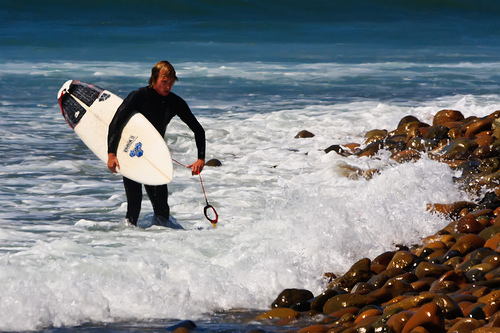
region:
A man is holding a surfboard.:
[50, 53, 226, 235]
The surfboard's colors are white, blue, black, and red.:
[50, 71, 175, 186]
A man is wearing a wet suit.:
[100, 71, 207, 231]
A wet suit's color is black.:
[100, 76, 207, 236]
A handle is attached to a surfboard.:
[162, 145, 222, 230]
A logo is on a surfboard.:
[121, 131, 150, 163]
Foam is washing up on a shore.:
[0, 85, 499, 332]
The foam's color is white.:
[0, 85, 498, 332]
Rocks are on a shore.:
[160, 96, 498, 332]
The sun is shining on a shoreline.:
[0, 51, 498, 331]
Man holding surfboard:
[87, 71, 202, 249]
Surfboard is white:
[66, 62, 191, 197]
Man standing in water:
[79, 86, 219, 230]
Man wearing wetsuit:
[98, 42, 163, 226]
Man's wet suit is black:
[60, 60, 192, 247]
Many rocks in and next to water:
[368, 86, 465, 278]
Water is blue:
[228, 38, 414, 88]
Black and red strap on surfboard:
[119, 110, 248, 252]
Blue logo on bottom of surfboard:
[127, 137, 164, 194]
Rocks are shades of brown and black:
[373, 254, 446, 329]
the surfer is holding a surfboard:
[53, 41, 298, 276]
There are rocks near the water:
[73, 29, 491, 330]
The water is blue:
[25, 9, 432, 264]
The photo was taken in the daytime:
[30, 8, 465, 289]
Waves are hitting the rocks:
[221, 85, 496, 322]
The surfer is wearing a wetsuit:
[56, 37, 276, 267]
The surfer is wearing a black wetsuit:
[50, 45, 260, 290]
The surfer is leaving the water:
[62, 32, 307, 284]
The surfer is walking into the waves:
[15, 16, 457, 324]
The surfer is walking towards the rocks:
[44, 36, 476, 323]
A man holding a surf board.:
[36, 51, 245, 279]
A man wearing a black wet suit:
[76, 44, 229, 296]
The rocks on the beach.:
[347, 76, 497, 330]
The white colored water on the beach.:
[50, 129, 439, 282]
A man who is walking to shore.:
[51, 55, 274, 219]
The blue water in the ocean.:
[36, 36, 480, 268]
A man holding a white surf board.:
[48, 42, 315, 325]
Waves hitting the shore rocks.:
[270, 112, 499, 293]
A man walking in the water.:
[40, 52, 315, 317]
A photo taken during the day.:
[31, 27, 416, 299]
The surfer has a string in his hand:
[121, 29, 318, 310]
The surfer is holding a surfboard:
[18, 51, 219, 258]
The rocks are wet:
[41, 24, 493, 330]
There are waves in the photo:
[60, 85, 425, 312]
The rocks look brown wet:
[280, 119, 474, 315]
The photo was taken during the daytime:
[55, 21, 484, 330]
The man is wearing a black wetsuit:
[36, 17, 364, 279]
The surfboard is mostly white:
[30, 40, 267, 293]